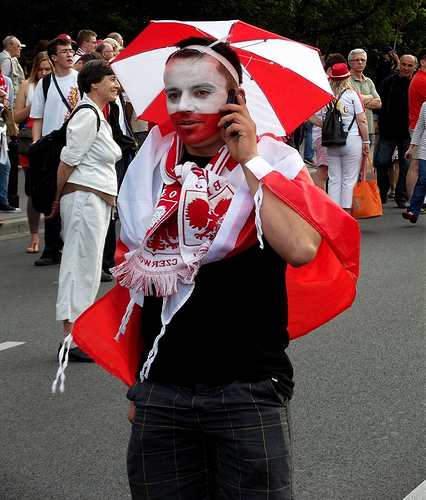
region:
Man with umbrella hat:
[73, 15, 360, 498]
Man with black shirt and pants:
[75, 20, 362, 493]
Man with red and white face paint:
[73, 15, 360, 498]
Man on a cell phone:
[70, 17, 362, 498]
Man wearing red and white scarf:
[71, 18, 360, 498]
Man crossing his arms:
[339, 47, 380, 221]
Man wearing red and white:
[76, 15, 363, 495]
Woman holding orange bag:
[317, 62, 380, 238]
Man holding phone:
[72, 17, 361, 498]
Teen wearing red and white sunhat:
[73, 17, 362, 498]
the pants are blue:
[132, 383, 299, 497]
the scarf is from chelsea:
[129, 159, 261, 265]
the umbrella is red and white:
[106, 10, 337, 144]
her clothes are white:
[29, 103, 124, 332]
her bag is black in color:
[318, 106, 346, 154]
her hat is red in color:
[324, 63, 353, 82]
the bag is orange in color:
[356, 174, 393, 217]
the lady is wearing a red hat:
[305, 50, 357, 87]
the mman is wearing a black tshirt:
[178, 262, 331, 353]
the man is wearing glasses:
[56, 33, 80, 62]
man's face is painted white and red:
[161, 46, 257, 150]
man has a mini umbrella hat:
[106, 14, 331, 138]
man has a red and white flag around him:
[67, 136, 366, 376]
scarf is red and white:
[120, 134, 236, 287]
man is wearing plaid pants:
[121, 361, 299, 498]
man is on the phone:
[214, 78, 263, 172]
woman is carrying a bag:
[352, 148, 395, 221]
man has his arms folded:
[353, 82, 388, 115]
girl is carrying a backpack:
[321, 91, 364, 155]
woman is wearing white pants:
[50, 170, 116, 334]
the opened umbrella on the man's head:
[104, 19, 337, 138]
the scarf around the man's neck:
[108, 131, 258, 295]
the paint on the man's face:
[163, 55, 229, 145]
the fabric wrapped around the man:
[51, 134, 360, 395]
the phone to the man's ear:
[222, 88, 246, 136]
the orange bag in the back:
[351, 150, 383, 220]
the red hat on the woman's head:
[329, 63, 353, 80]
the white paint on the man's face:
[161, 57, 228, 114]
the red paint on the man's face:
[169, 109, 223, 144]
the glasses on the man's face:
[54, 47, 74, 57]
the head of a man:
[163, 51, 252, 145]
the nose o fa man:
[170, 91, 199, 122]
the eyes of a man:
[151, 66, 236, 114]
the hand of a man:
[212, 47, 291, 167]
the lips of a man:
[164, 114, 225, 151]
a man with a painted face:
[167, 56, 274, 136]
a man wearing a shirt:
[117, 126, 376, 399]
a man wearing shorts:
[112, 368, 352, 484]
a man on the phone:
[168, 47, 325, 169]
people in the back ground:
[30, 28, 279, 258]